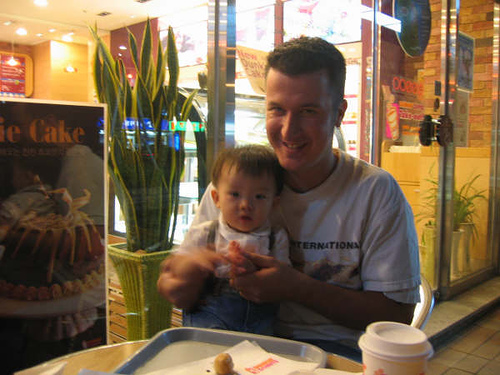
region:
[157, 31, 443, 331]
a man holding a baby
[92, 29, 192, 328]
a tall plant in green pot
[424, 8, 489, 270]
glass doors with a silver frame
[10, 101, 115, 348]
a sign advertising cake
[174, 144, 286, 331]
a baby boy clapping his hands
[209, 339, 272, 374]
a doughnut on a napkin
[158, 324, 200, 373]
a gray tray on a table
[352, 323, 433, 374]
a paper cup with a lid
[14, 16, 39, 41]
a bright light in the ceiling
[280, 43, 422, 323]
a man wearing white t-shirt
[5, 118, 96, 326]
a large ad for cake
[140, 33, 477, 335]
a man and a boy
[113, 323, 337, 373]
a food tray with a morsel on it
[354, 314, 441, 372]
a drink with a lid on it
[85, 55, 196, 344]
a tall potted plant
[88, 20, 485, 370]
a man sitting in a restaurant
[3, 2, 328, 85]
a brightly lighted ceiling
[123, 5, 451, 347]
man in a t-shirt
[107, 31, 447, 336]
a man and boy with hands in motion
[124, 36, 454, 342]
two people looking at the camera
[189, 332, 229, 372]
Appetizers on a tray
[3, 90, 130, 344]
Standing sign advertising a cake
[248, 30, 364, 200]
Smiling face of young father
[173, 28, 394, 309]
Young father holding his son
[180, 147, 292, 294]
Child held by his father looks surprised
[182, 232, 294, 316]
Father's hand holding food and his son's hand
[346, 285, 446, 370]
Insulated cup from restaurant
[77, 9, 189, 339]
Large potted plant in green vase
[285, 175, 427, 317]
White tee shirt of man mentioning something international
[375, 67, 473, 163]
Door with cling sign advertising Dunkin Donuts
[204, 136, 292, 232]
baby with brown hair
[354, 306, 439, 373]
paper cup with a white lid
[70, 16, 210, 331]
tall green plant behind the man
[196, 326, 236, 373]
food on the grey trey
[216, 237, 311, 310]
man is holding the baby's hand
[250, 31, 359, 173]
the man has brown hair and is smiling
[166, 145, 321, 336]
the baby is sitting on the man's lap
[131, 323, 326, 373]
white napkin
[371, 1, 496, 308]
door to coffee shop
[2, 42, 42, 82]
light fixture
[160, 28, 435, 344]
Man and baby sitting at table.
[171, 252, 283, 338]
Baby wearing blue jeans.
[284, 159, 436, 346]
Man wearing white shirt.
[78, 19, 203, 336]
Tall green plant in tall green planter.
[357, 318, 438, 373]
Cup with white lid sitting on table.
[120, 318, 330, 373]
Gray tray sitting on table.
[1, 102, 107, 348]
Advertising sign with picture of cake.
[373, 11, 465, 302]
Door to enter and exit building.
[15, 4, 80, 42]
Lights embedded in building's ceiling.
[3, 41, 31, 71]
Light hanging from building's ceiling.